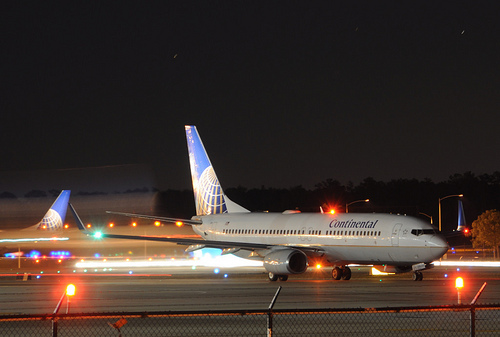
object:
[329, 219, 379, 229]
continental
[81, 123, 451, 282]
plane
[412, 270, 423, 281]
landing gear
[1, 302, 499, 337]
fence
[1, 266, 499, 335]
runway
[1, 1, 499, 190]
sky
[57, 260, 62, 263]
lights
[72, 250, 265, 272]
glare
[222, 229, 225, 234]
windows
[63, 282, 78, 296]
light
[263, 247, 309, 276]
engine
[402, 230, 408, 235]
star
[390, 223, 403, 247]
door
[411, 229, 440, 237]
windshield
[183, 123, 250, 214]
tail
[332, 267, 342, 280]
wheels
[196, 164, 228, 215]
globe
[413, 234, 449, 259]
nose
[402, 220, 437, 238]
cockpit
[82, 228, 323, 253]
wing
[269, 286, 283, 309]
pole